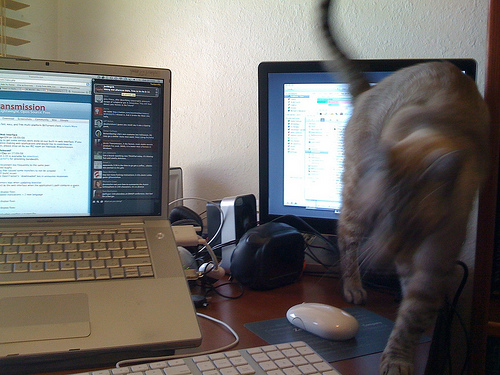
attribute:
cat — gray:
[332, 56, 464, 361]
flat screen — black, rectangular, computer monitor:
[251, 55, 484, 237]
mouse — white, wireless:
[281, 286, 399, 360]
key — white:
[266, 352, 281, 357]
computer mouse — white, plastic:
[286, 301, 360, 343]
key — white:
[223, 348, 241, 358]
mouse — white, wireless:
[284, 301, 359, 341]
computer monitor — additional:
[254, 55, 484, 225]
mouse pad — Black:
[244, 300, 402, 368]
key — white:
[314, 361, 324, 372]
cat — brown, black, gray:
[305, 0, 494, 374]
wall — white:
[206, 16, 276, 68]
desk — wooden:
[144, 224, 356, 354]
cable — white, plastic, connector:
[169, 216, 224, 271]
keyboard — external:
[77, 337, 341, 373]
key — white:
[289, 337, 306, 347]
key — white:
[191, 354, 210, 363]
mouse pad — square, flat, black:
[287, 299, 357, 350]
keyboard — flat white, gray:
[68, 341, 343, 373]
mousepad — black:
[242, 302, 394, 364]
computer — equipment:
[36, 59, 160, 271]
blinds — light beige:
[4, 0, 32, 57]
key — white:
[296, 344, 315, 356]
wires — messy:
[203, 234, 235, 298]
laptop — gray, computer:
[4, 48, 201, 369]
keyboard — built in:
[0, 235, 154, 285]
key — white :
[206, 351, 226, 361]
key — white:
[281, 342, 303, 362]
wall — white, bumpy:
[6, 3, 484, 221]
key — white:
[248, 348, 262, 356]